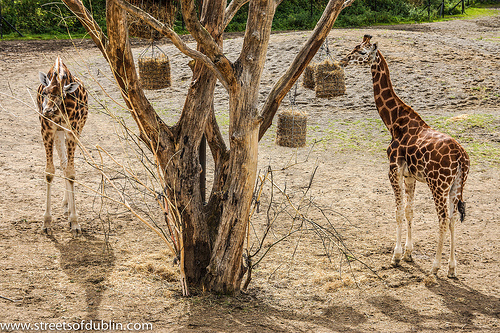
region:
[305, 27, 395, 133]
the giraffe is eating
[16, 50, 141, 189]
the giraffe is eating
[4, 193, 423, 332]
shadows on the ground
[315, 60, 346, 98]
A bail of hay for the giraffe to eat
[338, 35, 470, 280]
a giraffe eating hay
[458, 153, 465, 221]
the tail of the giraffe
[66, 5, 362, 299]
the base of the tree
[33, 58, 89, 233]
A giraffe next to the tree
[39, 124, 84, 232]
the legs of the giraffe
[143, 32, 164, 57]
the wire holding the hay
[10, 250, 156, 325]
the grass of the pasture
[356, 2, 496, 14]
green grass leading to a fence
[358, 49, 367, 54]
the eye of the giraffe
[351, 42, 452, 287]
A brown and white zebra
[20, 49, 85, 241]
A brown and white zebra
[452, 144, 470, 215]
A brown and white zebra's tail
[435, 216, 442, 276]
A brown and white zebra's feet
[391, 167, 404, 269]
A brown and white zebra's feet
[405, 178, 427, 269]
A brown and white zebra's feet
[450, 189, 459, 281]
A brown and white zebra's feet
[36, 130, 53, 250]
A brown and white zebra's feet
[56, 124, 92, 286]
A brown and white zebra's feet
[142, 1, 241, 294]
A big brown tree bark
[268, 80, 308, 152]
hay feeder hanging from a tree for giraffes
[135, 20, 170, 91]
hay feeder hanging from a tree for giraffes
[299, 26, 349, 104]
hay feeders hanging from a tree for giraffes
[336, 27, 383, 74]
the head of a giraffe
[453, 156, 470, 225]
the tail of a giraffe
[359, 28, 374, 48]
the horns of a giraffe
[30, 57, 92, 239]
a giraffe bending to eat a branch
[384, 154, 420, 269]
the front leg of a giraffe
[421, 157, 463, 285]
the hind legs of a giraffe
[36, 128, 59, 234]
the front leg of a giraffe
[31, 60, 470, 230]
Two giraffe are in ground.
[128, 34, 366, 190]
Feeding bag is hanging in tree.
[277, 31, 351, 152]
Hay is in the bag.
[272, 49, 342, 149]
Hay is brown color.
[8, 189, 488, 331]
Shadow falls on ground.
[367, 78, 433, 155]
Brown spots on ground.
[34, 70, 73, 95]
Two horns on giraffe head.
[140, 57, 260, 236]
Wood is brown color.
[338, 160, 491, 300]
Giraffe has four long legs.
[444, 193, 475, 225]
Black hairs on giraffe tail.